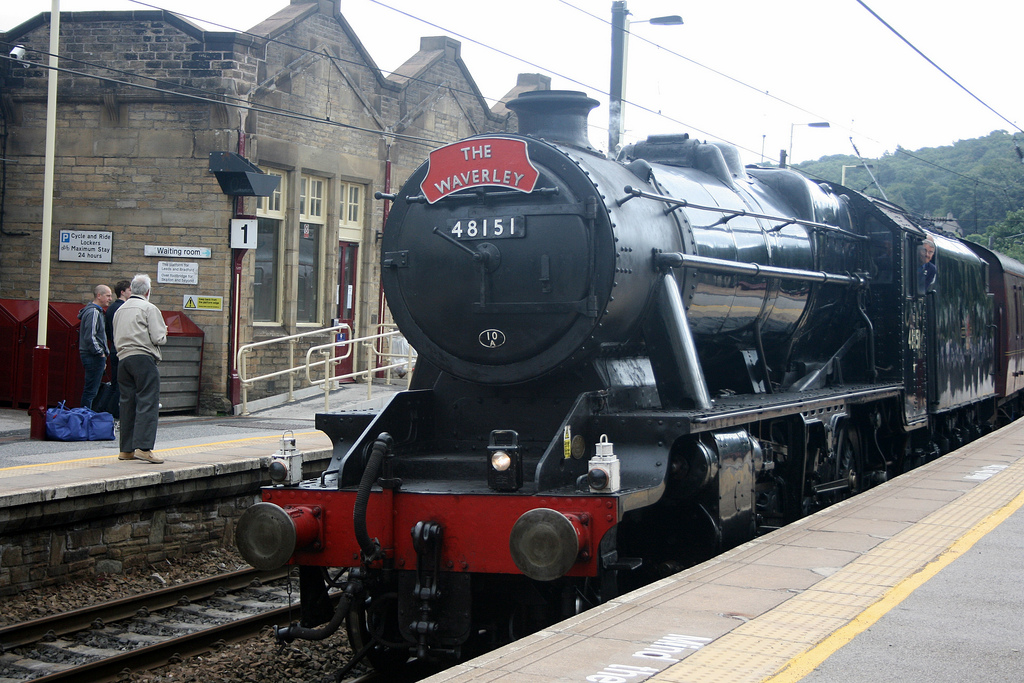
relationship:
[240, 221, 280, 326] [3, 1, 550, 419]
window on building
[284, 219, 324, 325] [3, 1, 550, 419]
window on a building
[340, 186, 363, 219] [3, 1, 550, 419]
window on a building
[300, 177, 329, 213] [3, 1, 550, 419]
window on a building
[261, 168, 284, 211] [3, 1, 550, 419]
window on a building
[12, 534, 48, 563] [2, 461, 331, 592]
stone in a wall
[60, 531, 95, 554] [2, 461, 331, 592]
stone in a wall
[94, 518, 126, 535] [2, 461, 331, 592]
stone in a wall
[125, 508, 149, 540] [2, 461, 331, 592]
stone in a wall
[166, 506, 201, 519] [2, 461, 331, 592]
stone in a wall